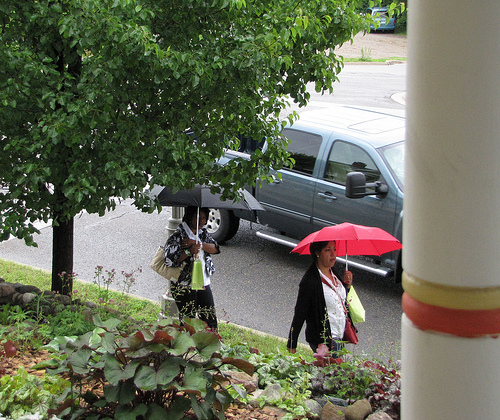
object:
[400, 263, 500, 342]
stripe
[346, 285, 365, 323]
bag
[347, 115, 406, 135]
sunroof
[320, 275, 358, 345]
purse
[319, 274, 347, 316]
strap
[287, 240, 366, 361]
person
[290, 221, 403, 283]
red umbrella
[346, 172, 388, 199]
mirror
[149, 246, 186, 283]
bag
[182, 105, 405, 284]
car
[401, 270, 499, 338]
ring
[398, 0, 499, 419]
pole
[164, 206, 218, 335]
person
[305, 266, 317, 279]
shoulder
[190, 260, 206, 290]
purse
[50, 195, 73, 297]
trunk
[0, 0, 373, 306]
tree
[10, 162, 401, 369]
pathway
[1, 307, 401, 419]
plants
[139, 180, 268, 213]
umbrella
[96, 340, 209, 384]
foliage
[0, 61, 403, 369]
road